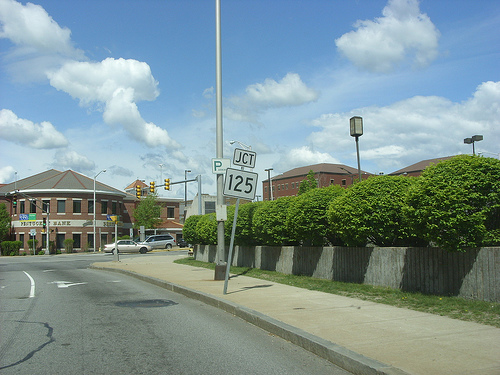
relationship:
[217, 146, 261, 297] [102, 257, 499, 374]
street sign on sidewalk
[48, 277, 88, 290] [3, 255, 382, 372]
arrow on street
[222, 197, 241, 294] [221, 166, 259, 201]
pillar holding number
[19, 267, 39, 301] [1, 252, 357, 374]
line on road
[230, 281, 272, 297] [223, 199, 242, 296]
shadow of pole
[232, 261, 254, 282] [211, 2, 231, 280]
shadow of pole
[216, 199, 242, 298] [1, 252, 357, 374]
street pole by side of road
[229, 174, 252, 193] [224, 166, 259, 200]
numbers on top of sign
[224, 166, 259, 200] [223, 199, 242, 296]
sign on pole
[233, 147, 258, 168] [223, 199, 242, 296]
sign on pole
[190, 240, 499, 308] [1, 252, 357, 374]
wall next to road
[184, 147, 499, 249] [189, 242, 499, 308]
bushes by fence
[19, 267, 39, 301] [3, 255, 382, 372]
line on street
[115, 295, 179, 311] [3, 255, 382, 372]
pothole in street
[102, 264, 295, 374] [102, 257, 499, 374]
curb by sidewalk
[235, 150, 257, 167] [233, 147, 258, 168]
jct on sign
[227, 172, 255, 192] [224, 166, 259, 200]
125 on sign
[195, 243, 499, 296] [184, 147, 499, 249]
shadows from bushes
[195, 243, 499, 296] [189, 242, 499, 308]
shadows on fence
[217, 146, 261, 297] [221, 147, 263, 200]
street sign for jct 125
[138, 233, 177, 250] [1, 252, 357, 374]
minivan on road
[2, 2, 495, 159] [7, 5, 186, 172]
sky has clouds